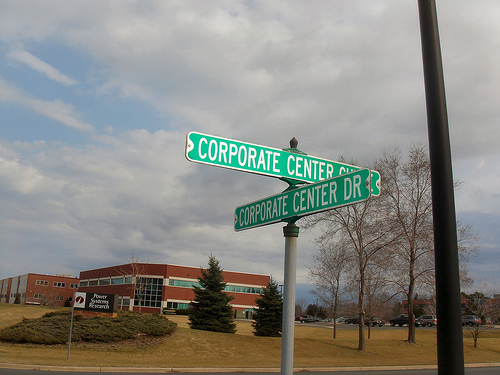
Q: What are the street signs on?
A: Pole.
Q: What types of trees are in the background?
A: Leafless.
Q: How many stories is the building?
A: 2.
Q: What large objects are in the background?
A: Mountains.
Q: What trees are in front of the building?
A: Pine trees.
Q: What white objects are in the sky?
A: Clouds.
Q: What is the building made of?
A: Bricks.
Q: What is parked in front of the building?
A: Cars.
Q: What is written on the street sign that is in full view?
A: Corporate Center Dr.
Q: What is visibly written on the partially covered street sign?
A: Corporate Center.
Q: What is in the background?
A: Building.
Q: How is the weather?
A: Cloudy.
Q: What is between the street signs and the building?
A: A field.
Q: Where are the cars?
A: Beside the building.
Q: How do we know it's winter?
A: The trees are leafless and the grass is brown.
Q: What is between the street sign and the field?
A: Road.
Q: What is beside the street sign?
A: Pole.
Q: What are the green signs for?
A: Directions.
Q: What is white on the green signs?
A: The text.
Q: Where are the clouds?
A: In the sky.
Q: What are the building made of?
A: Brick.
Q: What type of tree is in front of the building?
A: Pine.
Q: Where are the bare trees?
A: In front of the building.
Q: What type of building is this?
A: Office building.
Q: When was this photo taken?
A: Daytime.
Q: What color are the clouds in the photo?
A: White.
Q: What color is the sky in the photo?
A: Blue.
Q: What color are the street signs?
A: Green and white.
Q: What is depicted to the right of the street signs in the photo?
A: A pole.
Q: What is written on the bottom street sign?
A: Corporate Center Dr.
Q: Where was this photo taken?
A: At an office park.